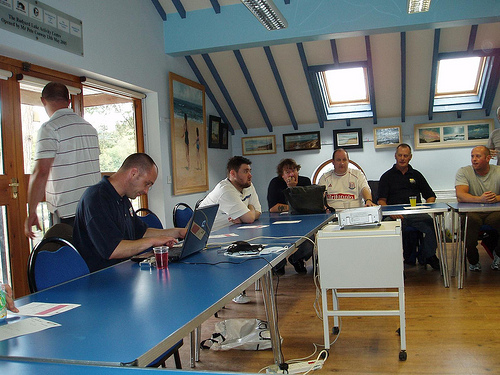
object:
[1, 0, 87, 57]
banner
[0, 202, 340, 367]
table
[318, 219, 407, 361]
white stand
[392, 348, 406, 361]
wheels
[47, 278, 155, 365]
table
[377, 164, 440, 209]
shirt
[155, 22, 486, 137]
roof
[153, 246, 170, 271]
cup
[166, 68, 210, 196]
artwork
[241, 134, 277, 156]
artwork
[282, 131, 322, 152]
artwork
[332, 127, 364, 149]
artwork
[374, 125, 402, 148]
artwork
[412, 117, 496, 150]
artwork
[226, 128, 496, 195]
wall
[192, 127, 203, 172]
person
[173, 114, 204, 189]
beach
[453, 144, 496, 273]
man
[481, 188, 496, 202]
hands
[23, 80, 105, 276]
man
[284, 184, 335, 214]
bag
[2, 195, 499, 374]
table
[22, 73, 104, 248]
men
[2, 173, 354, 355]
tables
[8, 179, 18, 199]
doorknob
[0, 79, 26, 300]
door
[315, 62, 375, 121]
window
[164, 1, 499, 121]
ceiling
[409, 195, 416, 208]
cup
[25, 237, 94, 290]
chair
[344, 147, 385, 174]
ground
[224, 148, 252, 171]
hair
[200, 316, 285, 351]
bag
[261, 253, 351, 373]
strip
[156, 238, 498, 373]
floor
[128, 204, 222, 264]
laptop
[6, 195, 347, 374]
table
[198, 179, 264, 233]
white shirt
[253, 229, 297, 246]
cord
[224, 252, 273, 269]
cord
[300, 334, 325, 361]
cord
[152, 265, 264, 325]
table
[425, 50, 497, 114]
skylights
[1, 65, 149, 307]
door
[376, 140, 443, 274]
man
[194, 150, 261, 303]
man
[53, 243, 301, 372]
table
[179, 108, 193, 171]
children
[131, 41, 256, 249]
wall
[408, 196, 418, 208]
juice